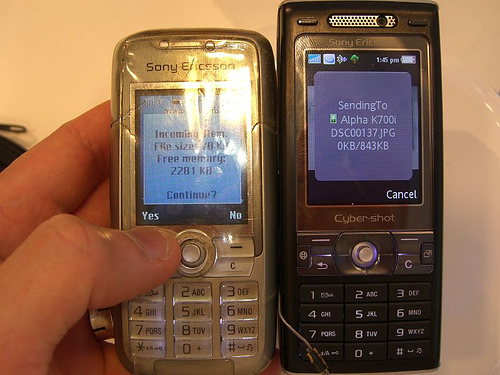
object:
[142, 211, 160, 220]
yes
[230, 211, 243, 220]
no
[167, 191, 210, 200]
continue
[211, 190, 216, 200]
question mark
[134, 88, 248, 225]
screen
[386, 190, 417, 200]
cancel icon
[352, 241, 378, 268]
button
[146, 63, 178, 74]
sony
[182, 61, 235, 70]
ecrisson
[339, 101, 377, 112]
sending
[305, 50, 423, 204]
screen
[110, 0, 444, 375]
phones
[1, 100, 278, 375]
hand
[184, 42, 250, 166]
glare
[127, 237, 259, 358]
buttons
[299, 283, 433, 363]
keypad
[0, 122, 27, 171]
pouch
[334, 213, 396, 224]
cyber-shot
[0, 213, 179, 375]
thumb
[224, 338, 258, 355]
key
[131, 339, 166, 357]
key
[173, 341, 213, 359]
key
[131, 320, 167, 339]
key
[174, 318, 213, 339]
key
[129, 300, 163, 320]
key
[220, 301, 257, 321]
key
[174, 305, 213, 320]
key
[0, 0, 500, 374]
photo